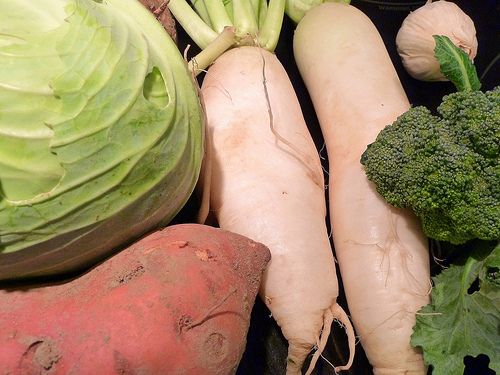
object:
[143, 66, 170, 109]
hole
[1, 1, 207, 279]
leaf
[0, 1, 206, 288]
cabbage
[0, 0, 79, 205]
curved edge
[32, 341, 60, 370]
dirt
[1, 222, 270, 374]
sweet potato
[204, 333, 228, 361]
marking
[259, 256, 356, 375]
bottom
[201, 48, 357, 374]
turnip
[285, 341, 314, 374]
root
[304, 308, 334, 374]
root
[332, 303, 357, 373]
root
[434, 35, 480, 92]
leaf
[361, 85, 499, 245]
broccoli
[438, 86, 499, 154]
floret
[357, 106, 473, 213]
floret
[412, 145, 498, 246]
floret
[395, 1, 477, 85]
garlic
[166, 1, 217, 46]
stalk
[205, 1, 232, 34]
stalk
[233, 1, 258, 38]
stalk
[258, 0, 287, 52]
stalk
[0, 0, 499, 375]
table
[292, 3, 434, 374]
turnip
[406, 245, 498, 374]
leaf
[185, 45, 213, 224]
root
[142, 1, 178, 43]
vegetable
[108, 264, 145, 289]
spot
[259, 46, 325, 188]
string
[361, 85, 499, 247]
spores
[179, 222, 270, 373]
edge